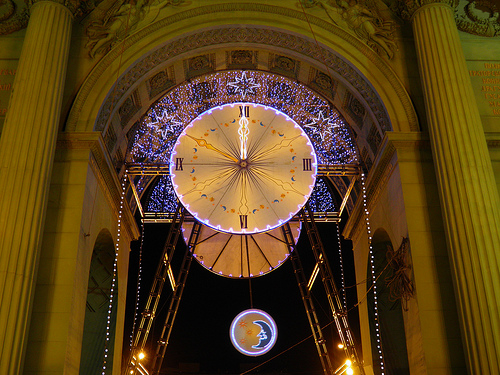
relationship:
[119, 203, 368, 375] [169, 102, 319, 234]
scaffolding leading to clock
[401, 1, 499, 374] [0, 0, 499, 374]
pillar in building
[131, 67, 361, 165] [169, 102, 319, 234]
display on clock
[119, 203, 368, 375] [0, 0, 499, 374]
scaffolding on building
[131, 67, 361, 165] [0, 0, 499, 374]
display on building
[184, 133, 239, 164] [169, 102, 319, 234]
hand on clock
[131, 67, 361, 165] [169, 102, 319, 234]
display around clock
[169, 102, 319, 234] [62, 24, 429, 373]
clock under archway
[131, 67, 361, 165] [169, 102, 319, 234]
display above clock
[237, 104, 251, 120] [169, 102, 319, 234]
12 on clock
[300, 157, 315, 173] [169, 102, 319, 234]
3 on clock